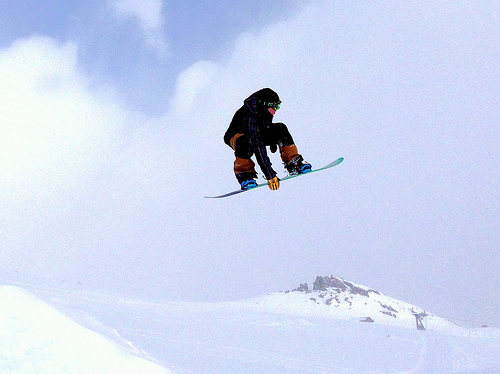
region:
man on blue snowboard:
[204, 86, 346, 204]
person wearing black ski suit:
[225, 88, 312, 193]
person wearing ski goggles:
[260, 98, 279, 110]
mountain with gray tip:
[287, 270, 461, 329]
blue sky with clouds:
[1, 1, 307, 116]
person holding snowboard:
[206, 152, 339, 200]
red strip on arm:
[226, 129, 245, 149]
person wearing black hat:
[245, 86, 277, 118]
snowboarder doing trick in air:
[200, 86, 345, 199]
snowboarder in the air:
[202, 85, 345, 196]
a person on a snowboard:
[206, 88, 345, 203]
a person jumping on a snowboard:
[213, 86, 343, 203]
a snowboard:
[204, 155, 344, 200]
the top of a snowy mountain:
[218, 273, 464, 343]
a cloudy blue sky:
[4, 3, 235, 105]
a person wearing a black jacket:
[211, 86, 318, 196]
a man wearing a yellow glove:
[221, 86, 316, 196]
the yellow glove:
[265, 175, 280, 189]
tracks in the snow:
[203, 324, 385, 372]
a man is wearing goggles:
[218, 85, 344, 200]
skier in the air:
[191, 68, 366, 205]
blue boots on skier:
[234, 163, 319, 187]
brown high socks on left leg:
[286, 143, 300, 154]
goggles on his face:
[243, 98, 295, 113]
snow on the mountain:
[296, 280, 427, 326]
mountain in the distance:
[301, 286, 443, 335]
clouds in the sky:
[8, 28, 205, 154]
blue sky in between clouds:
[173, 0, 278, 34]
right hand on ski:
[264, 175, 289, 199]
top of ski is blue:
[308, 146, 347, 173]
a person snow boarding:
[205, 73, 350, 196]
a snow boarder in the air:
[200, 85, 366, 205]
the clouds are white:
[3, 48, 128, 223]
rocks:
[294, 278, 378, 317]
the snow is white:
[161, 304, 295, 369]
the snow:
[193, 315, 302, 372]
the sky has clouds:
[22, 59, 114, 167]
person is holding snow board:
[256, 166, 287, 189]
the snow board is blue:
[314, 160, 343, 167]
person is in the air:
[172, 88, 363, 202]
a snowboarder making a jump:
[181, 66, 457, 324]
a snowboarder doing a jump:
[195, 75, 410, 340]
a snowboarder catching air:
[206, 75, 441, 307]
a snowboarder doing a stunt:
[187, 81, 442, 303]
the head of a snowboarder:
[249, 83, 288, 120]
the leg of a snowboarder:
[228, 135, 255, 193]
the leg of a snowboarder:
[277, 114, 302, 184]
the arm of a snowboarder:
[253, 141, 282, 196]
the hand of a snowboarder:
[263, 175, 285, 194]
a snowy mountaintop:
[266, 266, 440, 337]